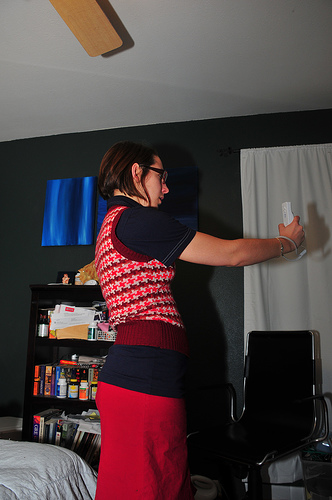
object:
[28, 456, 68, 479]
blanket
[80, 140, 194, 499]
woman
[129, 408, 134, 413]
red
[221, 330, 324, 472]
black chair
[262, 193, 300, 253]
wii remote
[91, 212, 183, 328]
vest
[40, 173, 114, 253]
painting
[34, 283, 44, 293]
shelf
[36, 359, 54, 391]
books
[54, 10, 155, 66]
ceiling fan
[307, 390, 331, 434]
silver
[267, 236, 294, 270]
bracelet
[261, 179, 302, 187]
curtains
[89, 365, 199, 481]
skirt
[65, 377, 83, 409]
bottle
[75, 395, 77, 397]
vitamins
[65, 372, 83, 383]
yellow top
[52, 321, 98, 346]
object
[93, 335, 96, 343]
bottle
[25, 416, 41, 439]
book